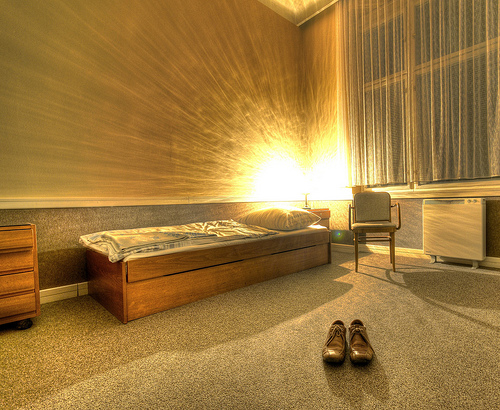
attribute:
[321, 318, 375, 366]
shoes — brown, tan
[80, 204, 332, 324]
bed — single, small, wood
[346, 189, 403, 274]
chair — wooden, unholstered, brown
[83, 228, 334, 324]
frame — wood, wooden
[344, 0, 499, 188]
drapes — lace, sheer, shut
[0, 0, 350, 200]
walls — cream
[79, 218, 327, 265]
covers — white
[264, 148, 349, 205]
light — yellow, shining, bright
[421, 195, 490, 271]
unit — white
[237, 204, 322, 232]
pillow — white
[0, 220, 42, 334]
dresser — wooden, brown, small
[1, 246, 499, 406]
carpet — grey, light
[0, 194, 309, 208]
rail — white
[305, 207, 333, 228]
nightstand — small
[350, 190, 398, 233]
seat — tan